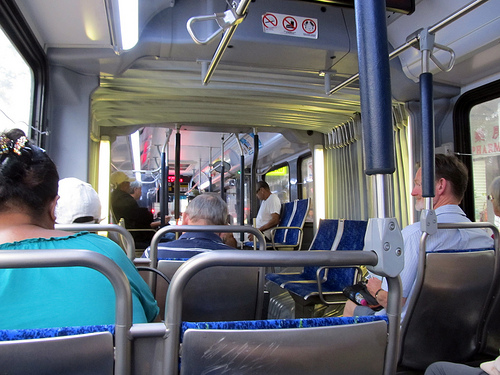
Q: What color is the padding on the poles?
A: Blue.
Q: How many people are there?
A: 7.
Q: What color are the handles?
A: Silver.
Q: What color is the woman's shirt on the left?
A: Turquoise.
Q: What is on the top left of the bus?
A: Light.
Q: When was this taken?
A: Daytime.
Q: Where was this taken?
A: On a bus.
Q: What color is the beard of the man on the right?
A: White.